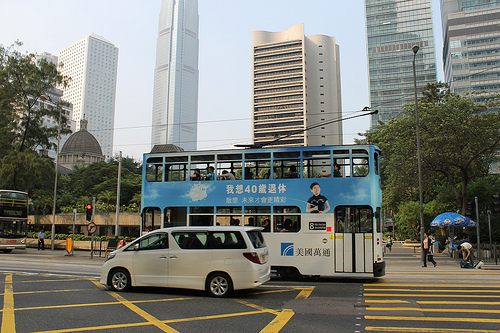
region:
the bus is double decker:
[145, 153, 387, 277]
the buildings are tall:
[56, 0, 495, 258]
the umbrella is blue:
[431, 213, 473, 230]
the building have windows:
[54, 0, 497, 170]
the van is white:
[101, 223, 271, 292]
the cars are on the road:
[103, 153, 385, 295]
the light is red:
[86, 203, 91, 220]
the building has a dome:
[61, 115, 103, 166]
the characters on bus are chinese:
[226, 183, 290, 203]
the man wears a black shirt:
[308, 198, 327, 211]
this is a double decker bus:
[130, 129, 401, 303]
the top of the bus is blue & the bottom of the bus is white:
[129, 131, 404, 283]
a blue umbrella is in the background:
[431, 208, 478, 242]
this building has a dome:
[56, 111, 108, 158]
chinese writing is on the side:
[208, 180, 307, 210]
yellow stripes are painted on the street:
[355, 272, 495, 330]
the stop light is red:
[83, 193, 98, 225]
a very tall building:
[235, 23, 352, 148]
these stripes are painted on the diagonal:
[14, 264, 256, 326]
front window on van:
[121, 226, 171, 256]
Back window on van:
[171, 221, 249, 260]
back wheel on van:
[206, 267, 233, 303]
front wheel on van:
[101, 263, 137, 295]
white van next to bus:
[83, 216, 268, 307]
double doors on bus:
[335, 201, 374, 278]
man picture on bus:
[303, 180, 330, 215]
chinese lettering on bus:
[218, 184, 291, 196]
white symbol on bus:
[185, 183, 214, 203]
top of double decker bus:
[141, 148, 368, 185]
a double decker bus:
[146, 145, 386, 280]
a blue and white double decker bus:
[134, 133, 378, 281]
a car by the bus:
[96, 211, 267, 302]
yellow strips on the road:
[367, 284, 464, 325]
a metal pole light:
[49, 96, 65, 258]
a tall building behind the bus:
[154, 1, 214, 138]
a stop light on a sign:
[83, 195, 93, 242]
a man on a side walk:
[38, 232, 48, 255]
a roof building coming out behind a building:
[57, 113, 103, 175]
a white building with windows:
[243, 23, 346, 142]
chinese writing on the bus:
[293, 245, 333, 259]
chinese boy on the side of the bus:
[307, 179, 329, 216]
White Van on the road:
[97, 213, 279, 295]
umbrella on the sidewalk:
[432, 204, 480, 229]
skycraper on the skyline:
[159, 1, 197, 147]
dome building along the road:
[61, 111, 101, 172]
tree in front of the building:
[360, 84, 487, 181]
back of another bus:
[2, 190, 26, 258]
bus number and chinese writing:
[220, 175, 290, 207]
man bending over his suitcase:
[452, 242, 482, 269]